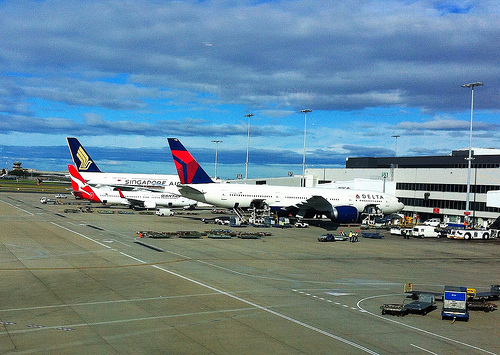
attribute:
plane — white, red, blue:
[167, 137, 405, 223]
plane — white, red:
[67, 164, 212, 209]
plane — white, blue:
[66, 135, 225, 194]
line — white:
[2, 314, 259, 336]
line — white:
[1, 291, 221, 312]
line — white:
[1, 199, 379, 354]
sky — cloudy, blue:
[0, 2, 498, 151]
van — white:
[412, 225, 440, 238]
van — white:
[422, 215, 439, 226]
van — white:
[156, 207, 174, 215]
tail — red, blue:
[166, 136, 213, 183]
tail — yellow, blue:
[65, 135, 100, 171]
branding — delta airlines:
[360, 191, 385, 199]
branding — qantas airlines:
[159, 194, 182, 199]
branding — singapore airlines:
[125, 180, 182, 187]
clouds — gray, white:
[1, 0, 499, 159]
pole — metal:
[465, 85, 476, 210]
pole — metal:
[301, 115, 309, 174]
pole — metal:
[245, 117, 251, 180]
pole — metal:
[215, 145, 219, 178]